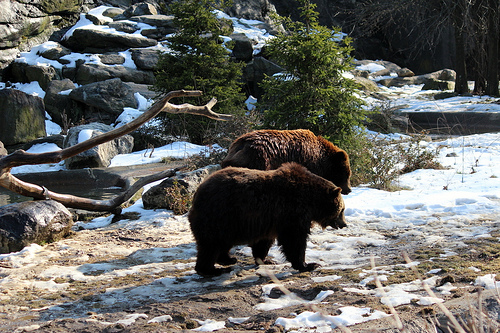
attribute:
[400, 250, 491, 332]
grass — dry blade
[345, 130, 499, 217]
snow — white , fluffy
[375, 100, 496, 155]
river — white, brown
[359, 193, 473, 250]
river — white, brown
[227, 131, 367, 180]
bear — brown 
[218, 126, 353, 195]
bear — Brown 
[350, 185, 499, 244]
snow — white 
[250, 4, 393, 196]
tree — green 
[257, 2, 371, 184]
tree —  green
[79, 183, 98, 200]
ripples — white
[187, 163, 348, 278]
bear — Brown , big 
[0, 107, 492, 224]
river — brown